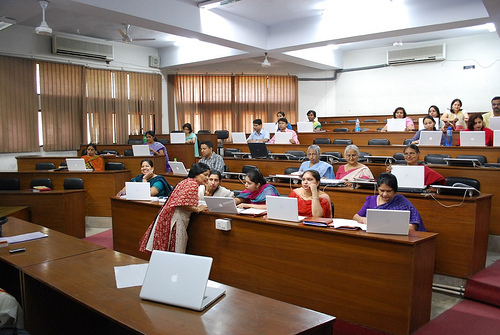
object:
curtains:
[0, 56, 299, 154]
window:
[0, 55, 298, 154]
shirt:
[287, 190, 332, 218]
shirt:
[357, 195, 428, 232]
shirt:
[335, 165, 374, 182]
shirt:
[130, 174, 172, 199]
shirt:
[198, 152, 224, 177]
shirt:
[186, 133, 199, 157]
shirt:
[81, 155, 105, 171]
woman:
[116, 159, 173, 197]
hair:
[200, 140, 214, 153]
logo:
[170, 273, 178, 282]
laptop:
[138, 249, 226, 312]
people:
[138, 162, 211, 254]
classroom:
[0, 0, 500, 335]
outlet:
[215, 218, 232, 231]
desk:
[109, 197, 440, 335]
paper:
[332, 219, 367, 231]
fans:
[246, 52, 287, 72]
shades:
[0, 54, 299, 154]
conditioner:
[52, 34, 115, 62]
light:
[35, 0, 53, 36]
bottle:
[446, 127, 453, 147]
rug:
[408, 258, 500, 335]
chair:
[63, 178, 84, 190]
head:
[141, 159, 154, 174]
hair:
[188, 162, 211, 179]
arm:
[181, 198, 202, 213]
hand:
[198, 204, 209, 213]